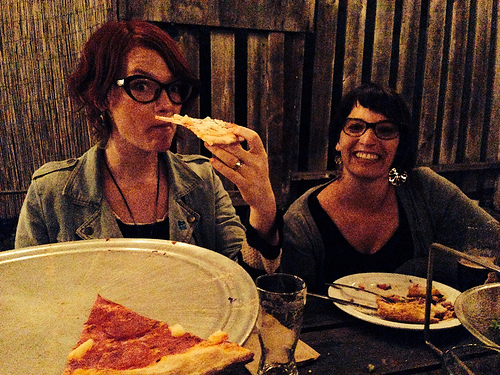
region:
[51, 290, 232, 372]
Piece of pizza on a pan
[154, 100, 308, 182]
Pizza in a hand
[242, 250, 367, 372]
Glass on a table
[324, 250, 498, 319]
Plate on a table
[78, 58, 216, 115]
Glasses on a woman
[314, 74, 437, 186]
Woman with brown hair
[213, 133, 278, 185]
Ring on a hand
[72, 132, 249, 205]
Necklace on a woman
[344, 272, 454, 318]
Food on a plate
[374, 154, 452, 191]
Earring on a woman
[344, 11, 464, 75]
this is the wall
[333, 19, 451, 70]
the wall is wooden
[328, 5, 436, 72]
the wood is thick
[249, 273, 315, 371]
this is a cup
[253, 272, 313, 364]
the cup is made of glass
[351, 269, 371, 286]
this is a plate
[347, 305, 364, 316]
the plate is white in color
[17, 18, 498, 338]
these are two women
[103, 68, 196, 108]
this is a pair of spectacles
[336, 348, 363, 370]
this is a table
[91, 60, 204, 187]
woman wearing dark glasses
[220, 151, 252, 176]
woman wearing ring on finger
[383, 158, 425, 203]
woman wearing large ear ring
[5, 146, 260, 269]
woman wearing a green jacket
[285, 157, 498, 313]
woman wearing a grey sweater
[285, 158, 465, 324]
woman wearing a black shirt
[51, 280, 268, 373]
A piece of pizza on pan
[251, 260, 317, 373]
an empty glass on table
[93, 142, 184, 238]
woman wearing a necklace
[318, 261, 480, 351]
partically eaten food on a plate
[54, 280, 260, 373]
Last piece of pizza on the plate.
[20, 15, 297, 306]
Woman eating slice of pizza.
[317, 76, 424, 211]
Woman smiling at the camera.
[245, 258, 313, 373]
Empty glass on the table.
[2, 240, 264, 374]
Pizza pan made of metal.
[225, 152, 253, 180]
Ring on the woman's finger.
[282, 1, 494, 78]
Wall made of wood.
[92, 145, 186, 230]
Necklace around woman's neck.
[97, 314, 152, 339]
Pepperoni on the pizza.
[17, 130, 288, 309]
Denim jacket on the woman.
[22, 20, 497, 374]
women seated at table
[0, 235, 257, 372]
pizza slice on tray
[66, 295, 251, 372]
slice of pepperoni pizza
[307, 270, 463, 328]
two utensils on white plate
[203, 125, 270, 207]
silver ring on hand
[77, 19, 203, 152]
woman in black glasses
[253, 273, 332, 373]
empty beer glass on table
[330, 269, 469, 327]
partially eaten food on plate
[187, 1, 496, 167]
wall of wood boards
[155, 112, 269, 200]
pizza slice in hand